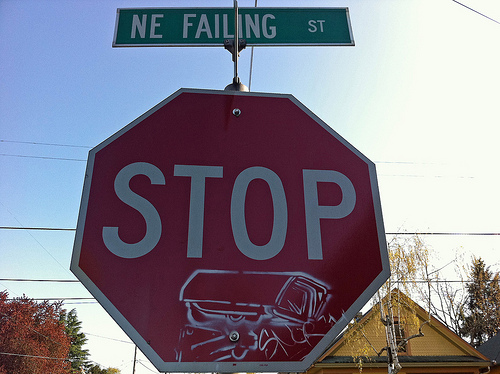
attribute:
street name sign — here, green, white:
[111, 6, 355, 47]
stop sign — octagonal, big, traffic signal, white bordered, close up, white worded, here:
[70, 87, 391, 373]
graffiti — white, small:
[178, 269, 347, 361]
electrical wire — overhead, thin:
[2, 225, 499, 236]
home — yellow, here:
[277, 287, 496, 372]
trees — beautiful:
[1, 289, 119, 372]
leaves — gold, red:
[0, 293, 72, 373]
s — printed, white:
[102, 162, 165, 259]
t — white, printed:
[173, 163, 223, 259]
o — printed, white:
[230, 165, 288, 260]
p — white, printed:
[302, 166, 356, 260]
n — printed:
[131, 13, 148, 38]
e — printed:
[149, 15, 165, 39]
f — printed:
[183, 13, 197, 37]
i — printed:
[214, 14, 220, 38]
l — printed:
[222, 13, 232, 39]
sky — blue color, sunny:
[0, 1, 499, 371]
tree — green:
[58, 307, 89, 374]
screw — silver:
[231, 106, 242, 118]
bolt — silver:
[227, 330, 240, 343]